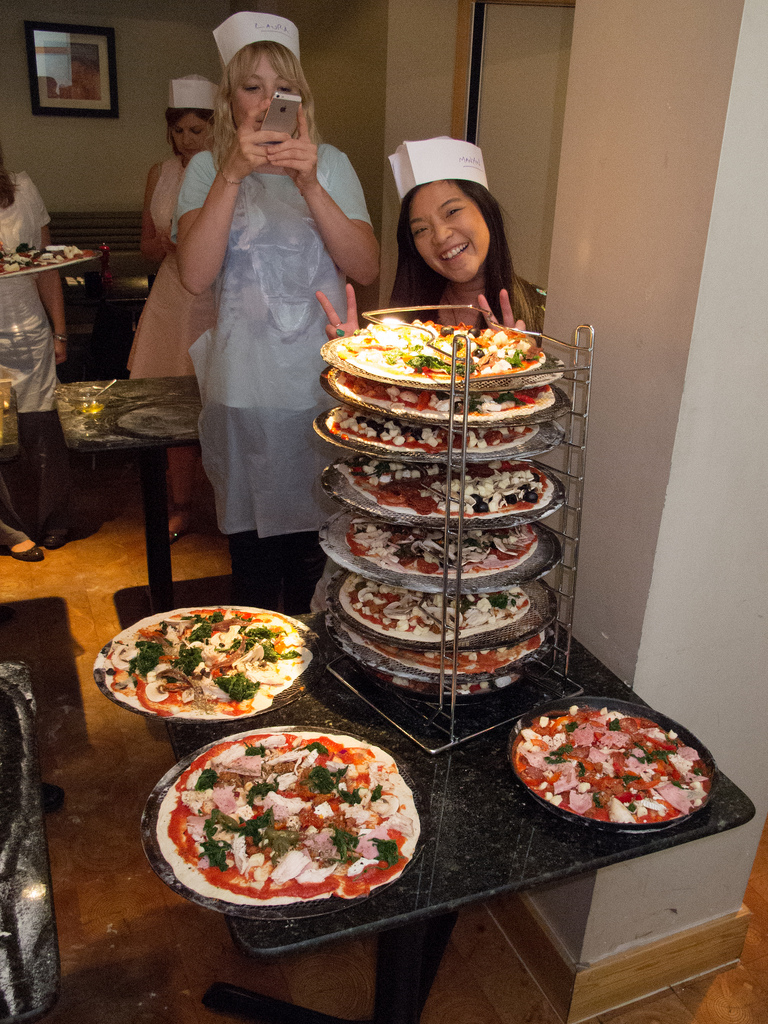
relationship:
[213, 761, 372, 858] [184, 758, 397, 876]
toppings on pizza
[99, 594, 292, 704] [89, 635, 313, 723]
uncooked pizza on metal tray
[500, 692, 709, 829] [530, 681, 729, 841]
pizza on tray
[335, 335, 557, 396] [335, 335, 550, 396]
pizza on tray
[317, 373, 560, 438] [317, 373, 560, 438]
pizza on tray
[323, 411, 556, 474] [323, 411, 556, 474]
pizza on tray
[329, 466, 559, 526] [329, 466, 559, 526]
pizza on tray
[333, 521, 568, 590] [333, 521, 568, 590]
pizza on tray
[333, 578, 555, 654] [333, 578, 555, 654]
pizza on tray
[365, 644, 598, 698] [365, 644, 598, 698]
pizza on tray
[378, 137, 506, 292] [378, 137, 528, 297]
head on girl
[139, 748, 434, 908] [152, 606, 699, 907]
pizza on table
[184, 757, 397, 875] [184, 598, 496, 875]
pizza on surface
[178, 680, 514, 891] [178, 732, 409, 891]
table under pizza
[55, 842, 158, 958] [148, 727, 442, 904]
ground under pizza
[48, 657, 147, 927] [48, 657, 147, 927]
light hitting ground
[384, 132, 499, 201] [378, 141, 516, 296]
chef hat on girl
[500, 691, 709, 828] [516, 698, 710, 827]
pizza in pan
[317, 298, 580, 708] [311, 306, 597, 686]
pans on pizza rack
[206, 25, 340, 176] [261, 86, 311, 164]
girl holding phone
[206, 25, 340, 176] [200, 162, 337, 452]
girl wearing an apron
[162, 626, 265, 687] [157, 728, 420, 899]
toppings on pizza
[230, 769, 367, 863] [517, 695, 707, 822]
toppings on pizza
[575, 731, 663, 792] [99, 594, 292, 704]
toppings on uncooked pizza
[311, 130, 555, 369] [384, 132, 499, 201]
girl wearing chef hat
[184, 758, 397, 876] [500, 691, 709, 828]
pizza near pizza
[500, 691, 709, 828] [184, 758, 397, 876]
pizza near pizza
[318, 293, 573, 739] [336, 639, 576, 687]
stack of pizza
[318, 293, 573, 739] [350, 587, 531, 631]
stack of pizza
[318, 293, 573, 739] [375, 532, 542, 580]
stack of pizza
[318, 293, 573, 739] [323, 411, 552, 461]
stack of pizza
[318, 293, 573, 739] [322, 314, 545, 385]
stack of pizza